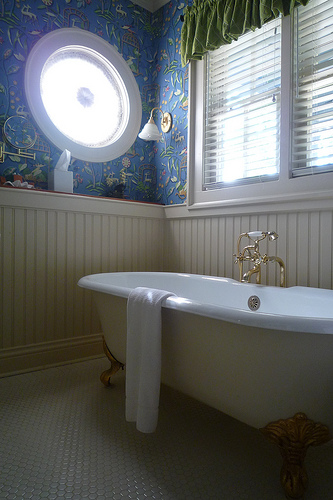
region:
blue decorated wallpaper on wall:
[3, 0, 197, 201]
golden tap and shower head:
[225, 221, 300, 293]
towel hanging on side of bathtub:
[112, 278, 198, 446]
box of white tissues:
[47, 145, 80, 201]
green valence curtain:
[178, 1, 332, 76]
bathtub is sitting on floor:
[66, 245, 329, 488]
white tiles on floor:
[6, 370, 163, 498]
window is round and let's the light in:
[20, 14, 143, 173]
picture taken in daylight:
[19, 5, 320, 182]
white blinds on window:
[197, 23, 332, 198]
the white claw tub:
[80, 265, 332, 466]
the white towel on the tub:
[122, 282, 170, 435]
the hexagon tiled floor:
[10, 403, 101, 492]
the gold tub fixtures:
[234, 227, 287, 285]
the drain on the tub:
[246, 295, 259, 309]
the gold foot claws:
[97, 335, 121, 392]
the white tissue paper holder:
[47, 148, 75, 194]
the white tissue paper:
[56, 150, 69, 169]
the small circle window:
[24, 21, 144, 161]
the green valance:
[177, 0, 282, 67]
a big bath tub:
[78, 268, 330, 497]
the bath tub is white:
[78, 269, 329, 433]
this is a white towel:
[125, 286, 165, 432]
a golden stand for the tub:
[262, 416, 331, 499]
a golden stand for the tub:
[92, 335, 127, 395]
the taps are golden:
[231, 221, 299, 291]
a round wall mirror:
[20, 18, 147, 160]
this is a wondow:
[181, 1, 331, 202]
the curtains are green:
[176, 0, 330, 57]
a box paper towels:
[33, 147, 97, 203]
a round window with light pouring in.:
[25, 21, 158, 161]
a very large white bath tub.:
[74, 254, 331, 448]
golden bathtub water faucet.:
[226, 226, 291, 292]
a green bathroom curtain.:
[175, 0, 317, 65]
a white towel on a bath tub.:
[117, 283, 184, 435]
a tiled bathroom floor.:
[0, 343, 331, 499]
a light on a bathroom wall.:
[132, 99, 180, 147]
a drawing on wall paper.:
[113, 158, 132, 191]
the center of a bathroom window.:
[71, 82, 100, 113]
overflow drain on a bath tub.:
[236, 295, 265, 319]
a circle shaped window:
[24, 28, 144, 160]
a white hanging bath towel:
[118, 284, 169, 436]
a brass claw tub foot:
[258, 412, 327, 497]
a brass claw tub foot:
[95, 333, 124, 389]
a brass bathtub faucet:
[234, 228, 288, 287]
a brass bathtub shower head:
[234, 225, 278, 280]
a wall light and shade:
[137, 104, 172, 144]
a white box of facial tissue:
[42, 150, 74, 194]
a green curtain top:
[178, 0, 328, 64]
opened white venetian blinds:
[206, 35, 281, 189]